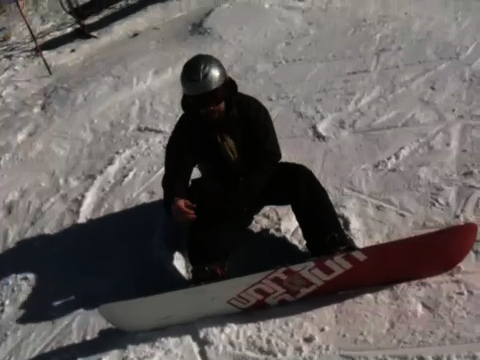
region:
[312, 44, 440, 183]
tracks in the white snow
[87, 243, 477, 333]
red and white snow board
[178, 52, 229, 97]
silver helmet on the man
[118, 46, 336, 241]
man sitting in the snow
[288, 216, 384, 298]
man's foot on the snow board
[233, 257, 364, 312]
words written on the bottom of the snowboard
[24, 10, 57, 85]
pole stuck in the ground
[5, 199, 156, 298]
shadow on the snow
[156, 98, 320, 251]
man wearing a black snow suit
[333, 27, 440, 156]
white snow on the ground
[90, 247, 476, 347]
Red and white snowboard.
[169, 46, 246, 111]
Silver helmet on a man.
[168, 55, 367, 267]
Man with black snow suit.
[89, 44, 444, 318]
Man sitting in the snow.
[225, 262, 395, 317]
Words UNITY on the snowboard.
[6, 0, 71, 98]
Stick in the snow.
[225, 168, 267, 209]
Covered hand in snowsuit.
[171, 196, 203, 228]
Uncovered hand in the snow.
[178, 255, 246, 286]
Man's snowboarding shoe.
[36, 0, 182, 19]
Shadow of a snow stick.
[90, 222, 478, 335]
Burgandy and silver surf board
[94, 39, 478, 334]
Man in black coat on surf board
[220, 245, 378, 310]
White lettering on bottom of surf board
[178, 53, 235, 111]
Silver and black helmet on man's head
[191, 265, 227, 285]
Black ski boot on man's foot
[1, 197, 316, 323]
Shadow of man in snow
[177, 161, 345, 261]
Black ski pants on man's legs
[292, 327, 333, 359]
Indentations in the snow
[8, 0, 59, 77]
Pole sitting in the snow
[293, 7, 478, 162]
Section of packed down snow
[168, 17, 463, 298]
A person with snowboard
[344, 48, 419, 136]
White color snow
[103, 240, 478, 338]
Red and white color of the snowboard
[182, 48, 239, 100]
A person wearing hat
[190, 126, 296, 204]
A person wearing black color snow dress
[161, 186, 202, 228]
Hand of the person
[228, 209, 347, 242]
Legs of the person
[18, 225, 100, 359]
Shadow of the person with snowboad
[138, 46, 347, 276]
A person with snow board sitting in the snow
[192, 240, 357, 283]
Pair of shoes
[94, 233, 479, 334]
red and white snowboard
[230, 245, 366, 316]
Unity logo on the snowboard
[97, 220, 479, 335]
snowboard on its side in the snow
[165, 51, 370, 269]
snowboarder sitting in the snow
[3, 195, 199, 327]
shadow of the snowboarder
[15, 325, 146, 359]
shadow of the snowboard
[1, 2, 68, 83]
trunk of a small tree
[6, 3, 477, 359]
packed snow covering the ground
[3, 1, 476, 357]
lots of tracks in the snow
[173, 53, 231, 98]
silver helmet